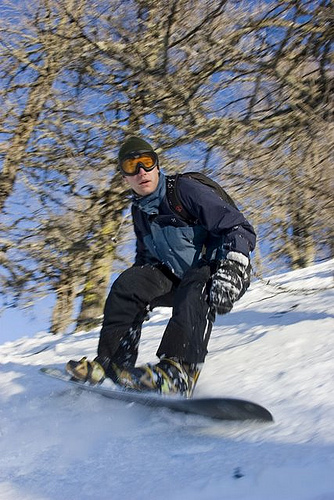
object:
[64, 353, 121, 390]
boots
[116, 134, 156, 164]
hat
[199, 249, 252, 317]
gloves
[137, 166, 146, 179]
nose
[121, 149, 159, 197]
man's face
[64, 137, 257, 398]
skier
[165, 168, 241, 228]
backpack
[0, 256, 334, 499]
snow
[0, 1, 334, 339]
tree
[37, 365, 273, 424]
snowboard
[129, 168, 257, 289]
jacket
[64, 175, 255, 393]
body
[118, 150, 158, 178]
goggles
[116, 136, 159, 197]
head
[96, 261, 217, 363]
pants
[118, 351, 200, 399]
feet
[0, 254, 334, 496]
hill